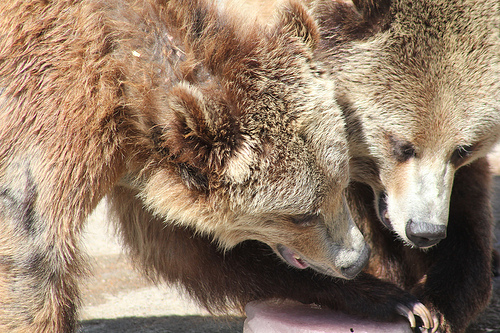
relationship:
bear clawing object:
[297, 0, 499, 333] [240, 295, 446, 329]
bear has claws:
[297, 0, 499, 333] [401, 309, 453, 330]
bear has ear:
[4, 5, 376, 330] [279, 4, 329, 60]